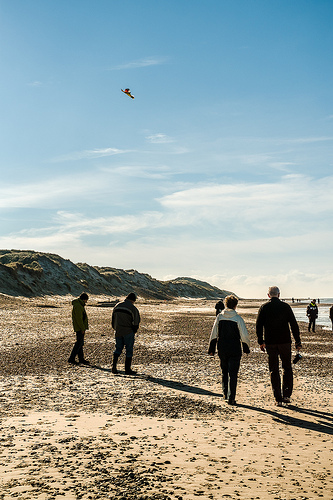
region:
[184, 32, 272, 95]
Sky is blue color.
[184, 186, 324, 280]
Clouds are white color.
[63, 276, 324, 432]
People are walking in sand.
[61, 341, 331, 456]
Shadow falls on sand.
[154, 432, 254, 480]
Sand is brown color.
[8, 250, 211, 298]
Small foot hill is seen.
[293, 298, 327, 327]
Water is blue color.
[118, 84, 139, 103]
Object is flying in air.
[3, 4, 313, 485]
Day time picture.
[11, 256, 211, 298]
Foot hill is brown color.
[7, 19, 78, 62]
this is the sky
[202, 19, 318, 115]
the sky is blue in color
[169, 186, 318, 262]
the sky has some clouds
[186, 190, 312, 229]
the clouds are white in color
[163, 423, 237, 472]
the ground is sandy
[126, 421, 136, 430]
the sand is white in color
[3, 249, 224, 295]
these are small hills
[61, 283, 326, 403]
these are some men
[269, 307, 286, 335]
the sweater is black in color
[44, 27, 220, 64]
this is the sky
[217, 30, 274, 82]
the sky is blue in color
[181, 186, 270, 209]
these are the clouds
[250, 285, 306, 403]
this is a man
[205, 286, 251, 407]
this is a lady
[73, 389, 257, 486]
this is the ground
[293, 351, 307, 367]
this is a camera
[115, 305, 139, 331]
this is a jacket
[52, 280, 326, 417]
People walking on the beach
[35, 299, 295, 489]
Brown rocks are scattered all over the sand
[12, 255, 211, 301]
There are large sand dunes on the beach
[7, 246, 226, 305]
There are plants growing on the sand dunes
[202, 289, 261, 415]
A woman in a black and white sweater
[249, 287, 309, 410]
A man is holding a camera by its strap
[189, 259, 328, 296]
The sky is blue with white clouds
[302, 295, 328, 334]
A man walking in a black and yellow jacket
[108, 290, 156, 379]
A man wearing a grey jacket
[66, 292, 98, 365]
A man wearing a black beanie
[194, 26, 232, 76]
part of the sky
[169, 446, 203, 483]
part of a ground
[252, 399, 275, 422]
part of a shade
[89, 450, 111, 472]
part of some stones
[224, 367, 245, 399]
part of a trouser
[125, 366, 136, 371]
part of a shoe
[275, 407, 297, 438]
part of a shade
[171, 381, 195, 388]
edge of a shadow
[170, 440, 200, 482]
part of a beach